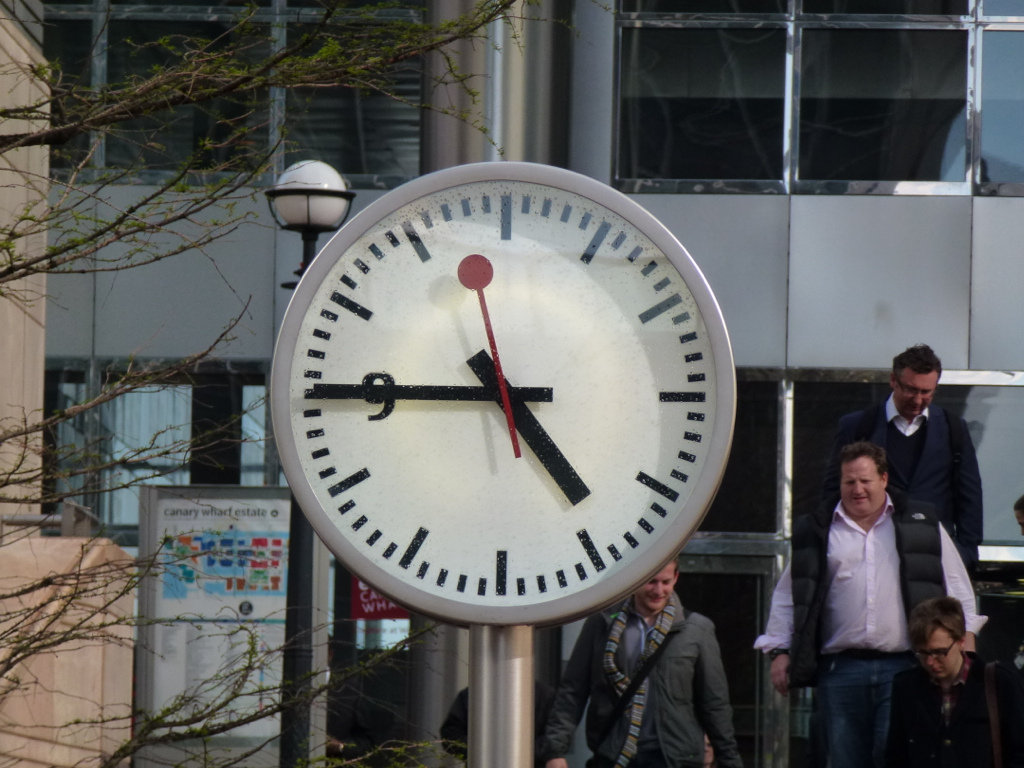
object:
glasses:
[903, 639, 963, 664]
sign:
[106, 468, 340, 754]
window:
[31, 0, 296, 202]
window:
[544, 0, 808, 212]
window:
[528, 508, 779, 768]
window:
[20, 334, 460, 618]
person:
[801, 333, 998, 595]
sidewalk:
[532, 704, 1024, 766]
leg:
[811, 689, 870, 767]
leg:
[863, 681, 915, 767]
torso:
[791, 511, 944, 672]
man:
[747, 430, 992, 767]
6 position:
[492, 542, 516, 602]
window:
[780, 0, 991, 200]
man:
[524, 532, 756, 768]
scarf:
[599, 587, 687, 768]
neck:
[635, 598, 671, 618]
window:
[263, 0, 466, 188]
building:
[5, 4, 1024, 768]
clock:
[216, 112, 813, 656]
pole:
[449, 612, 561, 767]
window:
[655, 343, 799, 552]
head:
[826, 432, 905, 517]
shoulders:
[813, 391, 904, 448]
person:
[874, 594, 1024, 767]